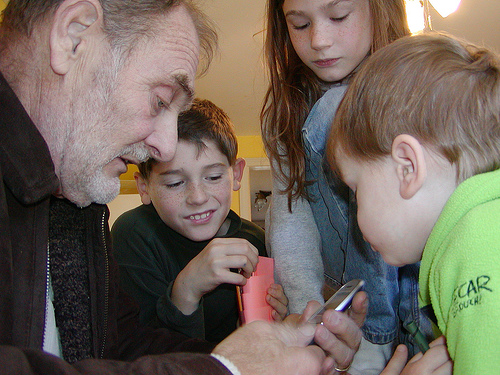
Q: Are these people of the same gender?
A: No, they are both male and female.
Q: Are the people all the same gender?
A: No, they are both male and female.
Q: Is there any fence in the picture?
A: No, there are no fences.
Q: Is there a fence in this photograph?
A: No, there are no fences.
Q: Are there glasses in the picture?
A: No, there are no glasses.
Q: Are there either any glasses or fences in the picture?
A: No, there are no glasses or fences.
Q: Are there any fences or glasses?
A: No, there are no glasses or fences.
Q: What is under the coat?
A: The shirt is under the coat.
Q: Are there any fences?
A: No, there are no fences.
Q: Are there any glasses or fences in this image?
A: No, there are no fences or glasses.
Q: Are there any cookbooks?
A: No, there are no cookbooks.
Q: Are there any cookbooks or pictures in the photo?
A: No, there are no cookbooks or pictures.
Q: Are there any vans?
A: No, there are no vans.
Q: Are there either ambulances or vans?
A: No, there are no vans or ambulances.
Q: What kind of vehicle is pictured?
A: The vehicle is a car.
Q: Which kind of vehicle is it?
A: The vehicle is a car.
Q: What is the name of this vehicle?
A: This is a car.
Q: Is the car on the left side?
A: Yes, the car is on the left of the image.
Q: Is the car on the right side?
A: No, the car is on the left of the image.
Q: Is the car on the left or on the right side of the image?
A: The car is on the left of the image.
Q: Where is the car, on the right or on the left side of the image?
A: The car is on the left of the image.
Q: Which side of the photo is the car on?
A: The car is on the left of the image.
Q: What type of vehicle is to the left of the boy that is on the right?
A: The vehicle is a car.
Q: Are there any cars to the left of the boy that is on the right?
A: Yes, there is a car to the left of the boy.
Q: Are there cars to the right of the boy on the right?
A: No, the car is to the left of the boy.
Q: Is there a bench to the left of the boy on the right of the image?
A: No, there is a car to the left of the boy.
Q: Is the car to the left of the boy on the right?
A: Yes, the car is to the left of the boy.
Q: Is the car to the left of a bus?
A: No, the car is to the left of the boy.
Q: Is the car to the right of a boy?
A: No, the car is to the left of a boy.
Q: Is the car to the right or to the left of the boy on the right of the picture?
A: The car is to the left of the boy.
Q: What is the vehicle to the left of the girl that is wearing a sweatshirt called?
A: The vehicle is a car.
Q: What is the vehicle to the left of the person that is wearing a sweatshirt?
A: The vehicle is a car.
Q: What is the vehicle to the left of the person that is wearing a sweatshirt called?
A: The vehicle is a car.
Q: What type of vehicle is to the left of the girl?
A: The vehicle is a car.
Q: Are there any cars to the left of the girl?
A: Yes, there is a car to the left of the girl.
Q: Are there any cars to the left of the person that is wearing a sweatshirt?
A: Yes, there is a car to the left of the girl.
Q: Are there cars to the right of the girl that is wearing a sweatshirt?
A: No, the car is to the left of the girl.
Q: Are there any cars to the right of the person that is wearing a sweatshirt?
A: No, the car is to the left of the girl.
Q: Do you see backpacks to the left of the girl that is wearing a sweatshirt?
A: No, there is a car to the left of the girl.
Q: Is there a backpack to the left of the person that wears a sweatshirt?
A: No, there is a car to the left of the girl.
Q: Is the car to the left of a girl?
A: Yes, the car is to the left of a girl.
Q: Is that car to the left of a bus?
A: No, the car is to the left of a girl.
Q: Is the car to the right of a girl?
A: No, the car is to the left of a girl.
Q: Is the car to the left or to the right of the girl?
A: The car is to the left of the girl.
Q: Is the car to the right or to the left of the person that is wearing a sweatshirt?
A: The car is to the left of the girl.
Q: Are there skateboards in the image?
A: No, there are no skateboards.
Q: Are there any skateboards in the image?
A: No, there are no skateboards.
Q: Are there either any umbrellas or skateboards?
A: No, there are no skateboards or umbrellas.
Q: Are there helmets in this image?
A: No, there are no helmets.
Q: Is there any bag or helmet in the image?
A: No, there are no helmets or bags.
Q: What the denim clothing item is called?
A: The clothing item is a jacket.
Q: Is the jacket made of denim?
A: Yes, the jacket is made of denim.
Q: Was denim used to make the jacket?
A: Yes, the jacket is made of denim.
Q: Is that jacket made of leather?
A: No, the jacket is made of jeans.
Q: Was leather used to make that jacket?
A: No, the jacket is made of jeans.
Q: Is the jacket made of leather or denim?
A: The jacket is made of denim.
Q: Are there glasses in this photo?
A: No, there are no glasses.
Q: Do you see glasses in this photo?
A: No, there are no glasses.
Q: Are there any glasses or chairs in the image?
A: No, there are no glasses or chairs.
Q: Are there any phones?
A: Yes, there is a phone.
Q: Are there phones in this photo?
A: Yes, there is a phone.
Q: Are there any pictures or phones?
A: Yes, there is a phone.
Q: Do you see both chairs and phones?
A: No, there is a phone but no chairs.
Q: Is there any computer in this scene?
A: No, there are no computers.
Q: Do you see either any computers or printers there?
A: No, there are no computers or printers.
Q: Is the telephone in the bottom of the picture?
A: Yes, the telephone is in the bottom of the image.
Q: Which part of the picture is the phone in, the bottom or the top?
A: The phone is in the bottom of the image.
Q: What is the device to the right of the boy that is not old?
A: The device is a phone.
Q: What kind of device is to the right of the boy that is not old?
A: The device is a phone.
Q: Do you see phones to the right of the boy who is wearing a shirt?
A: Yes, there is a phone to the right of the boy.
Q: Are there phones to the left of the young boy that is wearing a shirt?
A: No, the phone is to the right of the boy.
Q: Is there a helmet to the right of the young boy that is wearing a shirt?
A: No, there is a phone to the right of the boy.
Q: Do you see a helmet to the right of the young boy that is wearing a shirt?
A: No, there is a phone to the right of the boy.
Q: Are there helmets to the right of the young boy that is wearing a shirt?
A: No, there is a phone to the right of the boy.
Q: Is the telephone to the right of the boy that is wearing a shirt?
A: Yes, the telephone is to the right of the boy.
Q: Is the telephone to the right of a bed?
A: No, the telephone is to the right of the boy.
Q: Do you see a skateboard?
A: No, there are no skateboards.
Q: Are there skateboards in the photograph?
A: No, there are no skateboards.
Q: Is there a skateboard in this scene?
A: No, there are no skateboards.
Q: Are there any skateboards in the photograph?
A: No, there are no skateboards.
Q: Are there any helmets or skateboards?
A: No, there are no skateboards or helmets.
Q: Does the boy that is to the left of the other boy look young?
A: Yes, the boy is young.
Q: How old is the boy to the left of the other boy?
A: The boy is young.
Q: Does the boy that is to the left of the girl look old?
A: No, the boy is young.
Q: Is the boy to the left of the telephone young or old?
A: The boy is young.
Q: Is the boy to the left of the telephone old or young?
A: The boy is young.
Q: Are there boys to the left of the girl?
A: Yes, there is a boy to the left of the girl.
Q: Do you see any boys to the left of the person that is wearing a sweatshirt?
A: Yes, there is a boy to the left of the girl.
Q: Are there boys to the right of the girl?
A: No, the boy is to the left of the girl.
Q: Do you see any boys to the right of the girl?
A: No, the boy is to the left of the girl.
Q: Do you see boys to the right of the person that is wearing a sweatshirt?
A: No, the boy is to the left of the girl.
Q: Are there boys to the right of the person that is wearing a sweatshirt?
A: No, the boy is to the left of the girl.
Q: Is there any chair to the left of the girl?
A: No, there is a boy to the left of the girl.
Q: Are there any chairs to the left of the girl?
A: No, there is a boy to the left of the girl.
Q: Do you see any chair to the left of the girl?
A: No, there is a boy to the left of the girl.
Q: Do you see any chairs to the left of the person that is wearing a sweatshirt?
A: No, there is a boy to the left of the girl.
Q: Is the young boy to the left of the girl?
A: Yes, the boy is to the left of the girl.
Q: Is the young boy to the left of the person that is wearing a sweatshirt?
A: Yes, the boy is to the left of the girl.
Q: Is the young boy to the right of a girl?
A: No, the boy is to the left of a girl.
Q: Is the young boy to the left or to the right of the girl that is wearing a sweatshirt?
A: The boy is to the left of the girl.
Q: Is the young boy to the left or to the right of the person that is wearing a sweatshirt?
A: The boy is to the left of the girl.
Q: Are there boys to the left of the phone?
A: Yes, there is a boy to the left of the phone.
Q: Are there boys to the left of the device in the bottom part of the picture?
A: Yes, there is a boy to the left of the phone.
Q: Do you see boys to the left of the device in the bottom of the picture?
A: Yes, there is a boy to the left of the phone.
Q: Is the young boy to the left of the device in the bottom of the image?
A: Yes, the boy is to the left of the phone.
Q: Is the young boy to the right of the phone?
A: No, the boy is to the left of the phone.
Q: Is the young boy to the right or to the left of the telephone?
A: The boy is to the left of the telephone.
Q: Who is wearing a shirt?
A: The boy is wearing a shirt.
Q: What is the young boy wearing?
A: The boy is wearing a shirt.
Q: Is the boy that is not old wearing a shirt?
A: Yes, the boy is wearing a shirt.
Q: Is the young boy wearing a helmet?
A: No, the boy is wearing a shirt.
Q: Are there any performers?
A: No, there are no performers.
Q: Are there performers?
A: No, there are no performers.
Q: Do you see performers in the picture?
A: No, there are no performers.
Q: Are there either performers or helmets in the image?
A: No, there are no performers or helmets.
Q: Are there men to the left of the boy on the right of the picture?
A: Yes, there is a man to the left of the boy.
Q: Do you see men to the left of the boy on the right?
A: Yes, there is a man to the left of the boy.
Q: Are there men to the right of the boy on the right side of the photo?
A: No, the man is to the left of the boy.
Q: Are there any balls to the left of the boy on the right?
A: No, there is a man to the left of the boy.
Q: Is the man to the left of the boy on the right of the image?
A: Yes, the man is to the left of the boy.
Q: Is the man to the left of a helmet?
A: No, the man is to the left of the boy.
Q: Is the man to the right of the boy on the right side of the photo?
A: No, the man is to the left of the boy.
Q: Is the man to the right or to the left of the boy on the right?
A: The man is to the left of the boy.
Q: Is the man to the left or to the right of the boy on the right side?
A: The man is to the left of the boy.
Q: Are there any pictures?
A: No, there are no pictures.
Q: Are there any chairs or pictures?
A: No, there are no pictures or chairs.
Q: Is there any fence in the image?
A: No, there are no fences.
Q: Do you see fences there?
A: No, there are no fences.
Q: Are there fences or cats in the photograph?
A: No, there are no fences or cats.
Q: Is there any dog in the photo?
A: No, there are no dogs.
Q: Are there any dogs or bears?
A: No, there are no dogs or bears.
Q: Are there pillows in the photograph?
A: No, there are no pillows.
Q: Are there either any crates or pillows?
A: No, there are no pillows or crates.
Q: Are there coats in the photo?
A: Yes, there is a coat.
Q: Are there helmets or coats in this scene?
A: Yes, there is a coat.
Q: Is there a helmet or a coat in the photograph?
A: Yes, there is a coat.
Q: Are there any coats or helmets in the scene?
A: Yes, there is a coat.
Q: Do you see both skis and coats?
A: No, there is a coat but no skis.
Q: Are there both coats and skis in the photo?
A: No, there is a coat but no skis.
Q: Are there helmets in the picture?
A: No, there are no helmets.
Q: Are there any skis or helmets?
A: No, there are no helmets or skis.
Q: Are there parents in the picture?
A: No, there are no parents.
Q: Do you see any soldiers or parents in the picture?
A: No, there are no parents or soldiers.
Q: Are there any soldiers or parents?
A: No, there are no parents or soldiers.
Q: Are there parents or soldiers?
A: No, there are no parents or soldiers.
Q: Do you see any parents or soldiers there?
A: No, there are no parents or soldiers.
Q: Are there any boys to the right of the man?
A: Yes, there is a boy to the right of the man.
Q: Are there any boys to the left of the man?
A: No, the boy is to the right of the man.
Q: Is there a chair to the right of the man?
A: No, there is a boy to the right of the man.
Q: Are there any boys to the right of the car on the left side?
A: Yes, there is a boy to the right of the car.